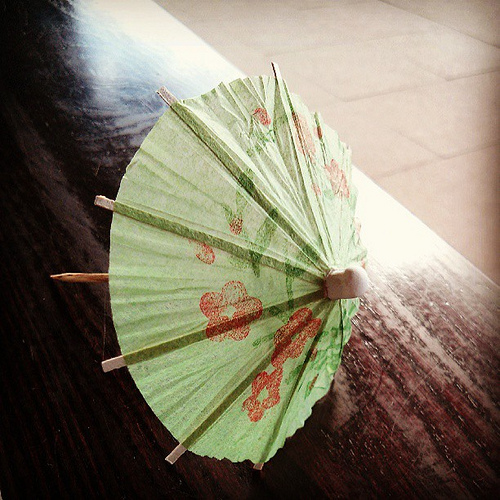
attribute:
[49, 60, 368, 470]
umbrella — green, paper, opened, sideways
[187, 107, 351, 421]
flowers — red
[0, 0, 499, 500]
table — wooden, stained, dark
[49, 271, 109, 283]
stake — sharp, wooden, toothpick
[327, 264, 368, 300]
knob — wooden, white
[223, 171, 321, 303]
leaf — green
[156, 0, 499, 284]
tile — white, light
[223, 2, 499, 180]
lines — gray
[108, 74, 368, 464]
paper — green, folded